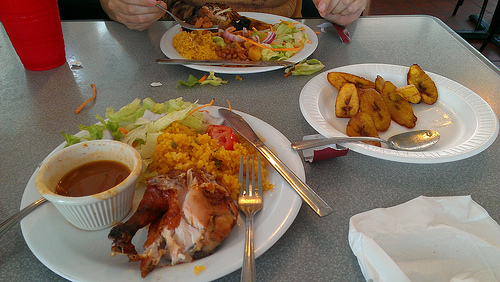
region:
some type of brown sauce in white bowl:
[55, 167, 124, 201]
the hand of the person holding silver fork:
[113, 0, 176, 25]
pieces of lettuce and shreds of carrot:
[173, 61, 318, 83]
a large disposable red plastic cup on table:
[5, 1, 67, 67]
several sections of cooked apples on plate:
[323, 65, 440, 126]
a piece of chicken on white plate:
[140, 172, 222, 267]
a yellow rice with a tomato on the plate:
[165, 126, 243, 172]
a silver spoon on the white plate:
[302, 132, 444, 153]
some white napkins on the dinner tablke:
[350, 195, 498, 274]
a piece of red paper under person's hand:
[315, 0, 373, 37]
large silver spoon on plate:
[304, 125, 461, 156]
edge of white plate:
[448, 139, 485, 152]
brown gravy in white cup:
[54, 168, 111, 184]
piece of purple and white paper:
[299, 130, 352, 167]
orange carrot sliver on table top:
[66, 85, 110, 112]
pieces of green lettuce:
[109, 92, 172, 126]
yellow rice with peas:
[143, 135, 234, 171]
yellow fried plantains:
[338, 77, 428, 122]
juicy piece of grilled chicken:
[141, 181, 249, 255]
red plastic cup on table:
[5, 15, 82, 77]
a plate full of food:
[11, 98, 315, 278]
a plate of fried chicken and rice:
[11, 96, 319, 279]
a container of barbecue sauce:
[32, 131, 144, 236]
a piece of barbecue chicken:
[106, 168, 242, 277]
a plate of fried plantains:
[303, 46, 499, 166]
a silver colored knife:
[216, 103, 334, 219]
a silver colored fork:
[233, 149, 270, 280]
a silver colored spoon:
[288, 124, 442, 156]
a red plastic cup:
[1, 0, 71, 75]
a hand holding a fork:
[75, 0, 221, 32]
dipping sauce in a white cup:
[33, 135, 135, 230]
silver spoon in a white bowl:
[291, 122, 441, 157]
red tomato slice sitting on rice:
[205, 120, 235, 150]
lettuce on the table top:
[169, 59, 322, 89]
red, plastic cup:
[1, 0, 69, 73]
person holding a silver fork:
[83, 0, 214, 36]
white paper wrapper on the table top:
[343, 188, 497, 280]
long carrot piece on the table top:
[68, 78, 99, 116]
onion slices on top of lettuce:
[219, 25, 279, 45]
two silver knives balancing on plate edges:
[149, 55, 336, 222]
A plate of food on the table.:
[11, 106, 286, 249]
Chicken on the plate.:
[120, 189, 241, 249]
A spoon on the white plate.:
[291, 118, 442, 160]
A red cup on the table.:
[5, 16, 80, 83]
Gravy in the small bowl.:
[41, 143, 138, 218]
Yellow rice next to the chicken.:
[169, 120, 261, 175]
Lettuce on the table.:
[51, 70, 276, 97]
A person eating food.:
[114, 0, 358, 77]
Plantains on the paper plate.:
[343, 63, 433, 125]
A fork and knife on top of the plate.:
[210, 83, 279, 278]